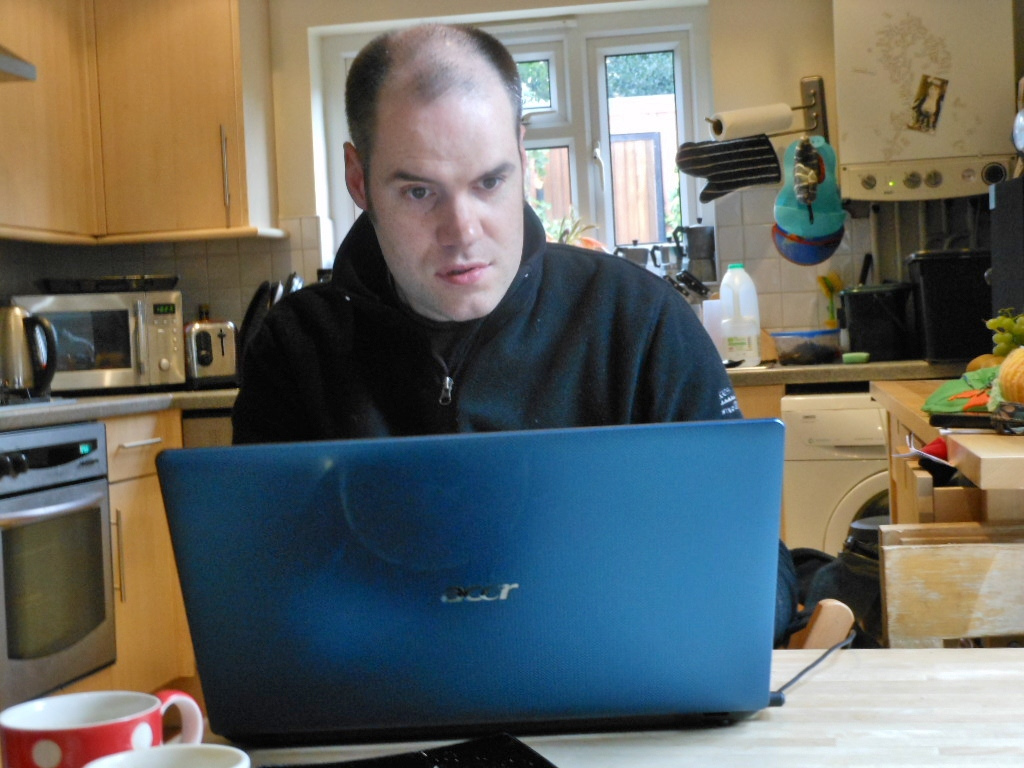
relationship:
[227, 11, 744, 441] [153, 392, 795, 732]
man looking at computer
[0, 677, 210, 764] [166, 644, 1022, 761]
mug on table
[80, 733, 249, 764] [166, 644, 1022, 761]
mug on table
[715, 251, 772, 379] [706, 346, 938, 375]
bottle on counter